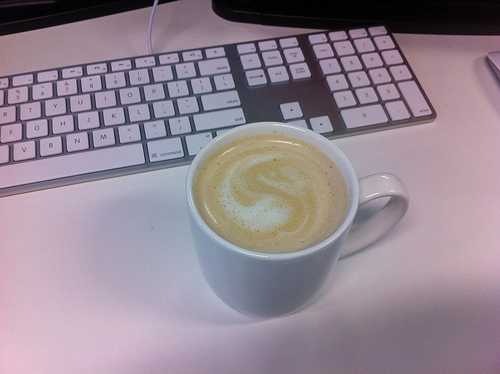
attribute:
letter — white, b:
[45, 139, 55, 155]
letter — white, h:
[55, 114, 66, 131]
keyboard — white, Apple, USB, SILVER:
[1, 24, 436, 199]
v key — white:
[10, 139, 39, 164]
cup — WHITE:
[183, 119, 407, 301]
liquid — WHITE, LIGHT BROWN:
[194, 129, 346, 250]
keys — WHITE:
[4, 22, 434, 191]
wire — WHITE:
[144, 6, 160, 50]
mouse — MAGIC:
[479, 54, 485, 62]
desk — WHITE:
[17, 8, 484, 358]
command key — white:
[144, 133, 184, 164]